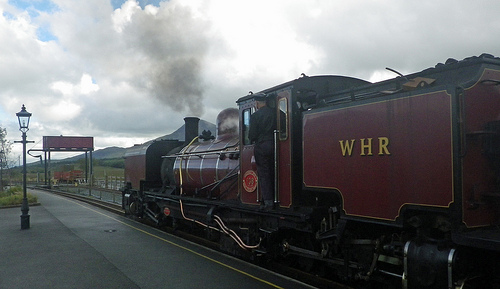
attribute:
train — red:
[126, 102, 493, 223]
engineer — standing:
[247, 94, 274, 206]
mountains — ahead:
[18, 119, 215, 174]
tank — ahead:
[14, 153, 28, 174]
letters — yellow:
[331, 129, 400, 169]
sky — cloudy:
[24, 5, 57, 42]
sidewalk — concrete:
[18, 189, 83, 213]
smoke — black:
[149, 13, 205, 98]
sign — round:
[235, 161, 262, 204]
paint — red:
[356, 164, 404, 193]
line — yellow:
[142, 231, 187, 254]